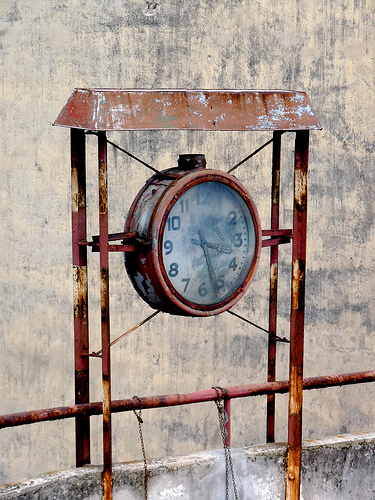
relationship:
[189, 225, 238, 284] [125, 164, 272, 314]
hands on clock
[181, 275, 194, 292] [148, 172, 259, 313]
numbers on clock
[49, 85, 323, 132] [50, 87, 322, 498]
top of metal casing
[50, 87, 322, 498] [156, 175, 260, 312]
metal casing holds clock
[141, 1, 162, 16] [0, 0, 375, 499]
chip missing from wall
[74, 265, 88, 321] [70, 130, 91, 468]
paint on pole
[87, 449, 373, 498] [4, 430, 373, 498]
paint on wall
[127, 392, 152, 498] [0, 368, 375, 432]
chain attached to rod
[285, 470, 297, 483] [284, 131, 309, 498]
screw on post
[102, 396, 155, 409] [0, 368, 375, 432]
soot on rod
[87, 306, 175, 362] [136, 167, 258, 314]
pole attached to clock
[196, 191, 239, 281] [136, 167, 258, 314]
dirt on front of clock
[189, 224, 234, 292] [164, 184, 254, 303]
hands on face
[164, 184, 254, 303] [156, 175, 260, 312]
face of clock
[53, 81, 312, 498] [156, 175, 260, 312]
tin stand for clock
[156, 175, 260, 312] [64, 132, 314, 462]
clock between posts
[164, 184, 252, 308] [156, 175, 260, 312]
glass on clock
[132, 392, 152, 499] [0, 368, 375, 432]
chain on rod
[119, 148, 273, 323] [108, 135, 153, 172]
clock between rods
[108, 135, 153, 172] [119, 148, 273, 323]
rods around clock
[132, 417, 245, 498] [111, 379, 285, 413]
wire hanging off rod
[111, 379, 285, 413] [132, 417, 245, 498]
rod with wire